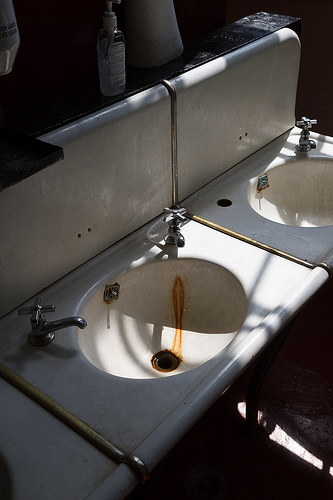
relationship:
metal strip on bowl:
[160, 78, 332, 282] [75, 255, 247, 384]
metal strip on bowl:
[0, 362, 150, 486] [75, 255, 247, 384]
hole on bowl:
[75, 233, 82, 239] [75, 255, 247, 384]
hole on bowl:
[86, 226, 93, 233] [75, 255, 247, 384]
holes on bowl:
[238, 132, 242, 141] [245, 154, 331, 227]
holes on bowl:
[244, 128, 247, 138] [245, 154, 331, 227]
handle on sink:
[288, 110, 314, 149] [179, 125, 332, 273]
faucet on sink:
[161, 205, 188, 249] [0, 208, 332, 482]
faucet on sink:
[16, 298, 88, 346] [0, 208, 332, 482]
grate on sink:
[104, 284, 122, 299] [0, 208, 332, 482]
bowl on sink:
[76, 256, 247, 378] [0, 208, 332, 482]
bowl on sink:
[248, 159, 332, 227] [179, 125, 332, 273]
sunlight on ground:
[235, 399, 332, 467] [101, 276, 332, 498]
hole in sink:
[215, 196, 233, 208] [171, 25, 331, 266]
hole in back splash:
[86, 226, 93, 233] [0, 27, 298, 313]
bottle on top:
[95, 0, 125, 96] [3, 9, 301, 189]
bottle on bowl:
[95, 0, 125, 96] [75, 255, 247, 384]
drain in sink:
[149, 344, 180, 371] [71, 242, 249, 379]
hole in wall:
[75, 233, 82, 239] [21, 136, 171, 273]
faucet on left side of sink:
[16, 298, 88, 344] [0, 208, 332, 482]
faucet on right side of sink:
[159, 205, 193, 249] [51, 241, 266, 397]